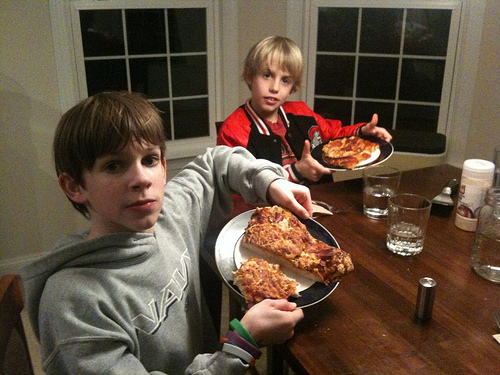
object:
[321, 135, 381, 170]
pizza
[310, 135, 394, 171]
plate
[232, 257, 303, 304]
chicken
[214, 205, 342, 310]
plate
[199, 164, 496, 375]
table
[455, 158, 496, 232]
can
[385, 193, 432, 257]
glass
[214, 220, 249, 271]
reflection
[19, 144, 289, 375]
sweatshirt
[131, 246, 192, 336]
logo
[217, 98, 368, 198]
jacket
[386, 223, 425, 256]
liquid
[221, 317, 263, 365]
bands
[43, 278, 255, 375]
arm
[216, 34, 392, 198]
boy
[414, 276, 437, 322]
salt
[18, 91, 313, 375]
boy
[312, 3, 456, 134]
window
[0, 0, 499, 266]
background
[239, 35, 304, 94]
hair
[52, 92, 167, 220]
hair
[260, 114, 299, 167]
shirt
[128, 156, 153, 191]
nose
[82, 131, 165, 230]
face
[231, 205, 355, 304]
pizza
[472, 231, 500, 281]
water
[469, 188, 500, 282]
jar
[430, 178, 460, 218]
spatula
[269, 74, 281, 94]
nose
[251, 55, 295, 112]
face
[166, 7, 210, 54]
pane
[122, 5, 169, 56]
pane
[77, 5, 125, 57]
pane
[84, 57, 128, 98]
pane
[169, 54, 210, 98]
pane